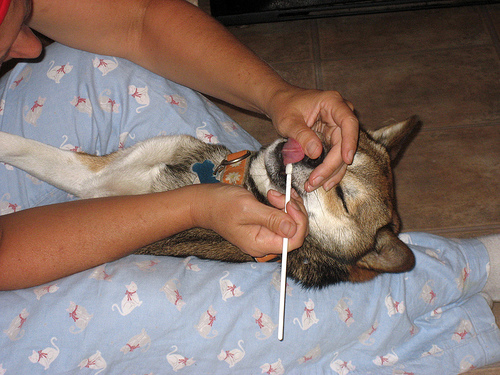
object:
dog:
[0, 110, 423, 292]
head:
[245, 112, 420, 290]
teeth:
[278, 153, 282, 158]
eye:
[333, 182, 351, 216]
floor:
[204, 0, 499, 243]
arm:
[27, 0, 362, 194]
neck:
[211, 145, 291, 264]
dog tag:
[190, 157, 225, 184]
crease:
[130, 0, 156, 46]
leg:
[9, 234, 500, 374]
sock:
[477, 232, 500, 302]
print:
[69, 86, 122, 118]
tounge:
[281, 136, 305, 167]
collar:
[190, 149, 253, 188]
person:
[0, 0, 500, 358]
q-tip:
[276, 162, 295, 342]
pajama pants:
[0, 40, 500, 375]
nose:
[301, 144, 326, 170]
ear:
[365, 113, 422, 161]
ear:
[354, 226, 417, 274]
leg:
[0, 35, 263, 227]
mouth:
[262, 137, 309, 201]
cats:
[128, 84, 150, 114]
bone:
[190, 158, 221, 184]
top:
[29, 50, 41, 60]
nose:
[7, 24, 43, 60]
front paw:
[0, 126, 33, 171]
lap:
[0, 25, 263, 211]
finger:
[275, 107, 324, 161]